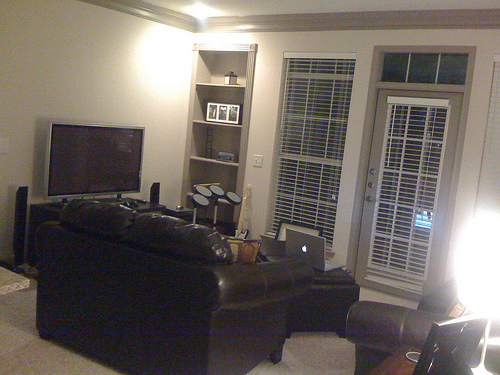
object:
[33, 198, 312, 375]
loveseat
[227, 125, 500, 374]
room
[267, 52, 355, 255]
blinds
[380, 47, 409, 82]
window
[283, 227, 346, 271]
laptop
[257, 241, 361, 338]
ottoman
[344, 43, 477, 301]
door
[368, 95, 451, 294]
blinds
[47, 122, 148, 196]
tv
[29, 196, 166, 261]
stand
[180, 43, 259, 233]
shelves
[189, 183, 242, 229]
drums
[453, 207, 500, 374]
lamp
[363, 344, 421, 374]
stand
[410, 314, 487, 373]
picture frame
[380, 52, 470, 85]
windows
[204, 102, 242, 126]
picture frame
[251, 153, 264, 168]
light switch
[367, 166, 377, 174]
lock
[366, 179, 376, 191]
lock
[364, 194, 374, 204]
lock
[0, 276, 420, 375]
floor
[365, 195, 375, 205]
handle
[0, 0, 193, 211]
wall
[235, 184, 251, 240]
guitar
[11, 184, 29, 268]
speaker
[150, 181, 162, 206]
speaker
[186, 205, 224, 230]
stand